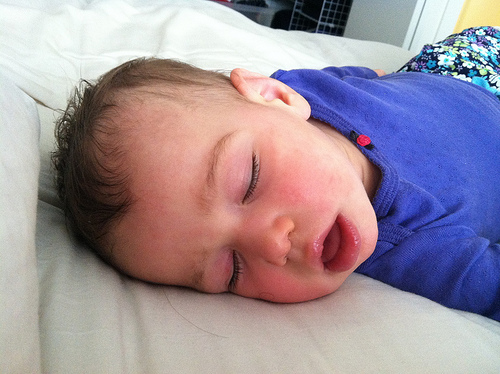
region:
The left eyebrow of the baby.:
[193, 235, 210, 292]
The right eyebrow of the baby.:
[207, 120, 234, 200]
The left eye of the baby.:
[221, 246, 243, 299]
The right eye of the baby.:
[244, 142, 261, 208]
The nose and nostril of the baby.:
[265, 210, 296, 277]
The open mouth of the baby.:
[307, 213, 363, 288]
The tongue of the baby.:
[323, 227, 339, 258]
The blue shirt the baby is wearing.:
[297, 50, 499, 292]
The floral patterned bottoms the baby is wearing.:
[402, 33, 499, 88]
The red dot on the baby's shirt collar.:
[349, 127, 379, 151]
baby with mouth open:
[71, 59, 397, 314]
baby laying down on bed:
[36, 81, 488, 337]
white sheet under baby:
[296, 309, 384, 372]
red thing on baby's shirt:
[353, 127, 394, 154]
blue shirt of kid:
[401, 89, 487, 191]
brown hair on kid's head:
[55, 86, 166, 226]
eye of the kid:
[226, 150, 284, 217]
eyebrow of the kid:
[184, 130, 242, 232]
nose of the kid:
[248, 204, 300, 276]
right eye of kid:
[211, 240, 251, 308]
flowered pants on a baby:
[397, 20, 497, 96]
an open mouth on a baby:
[305, 215, 360, 275]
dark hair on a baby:
[55, 60, 226, 270]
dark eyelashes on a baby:
[242, 152, 262, 199]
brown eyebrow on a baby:
[200, 126, 236, 191]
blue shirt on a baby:
[275, 50, 495, 307]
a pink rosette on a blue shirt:
[350, 127, 375, 147]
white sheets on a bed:
[36, 5, 488, 366]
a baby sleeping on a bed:
[50, 0, 495, 325]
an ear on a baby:
[221, 66, 311, 116]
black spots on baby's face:
[270, 127, 311, 187]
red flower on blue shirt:
[335, 116, 411, 158]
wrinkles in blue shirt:
[433, 191, 478, 233]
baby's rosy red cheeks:
[278, 155, 340, 220]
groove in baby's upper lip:
[289, 235, 317, 260]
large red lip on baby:
[338, 197, 378, 303]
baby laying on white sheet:
[48, 284, 242, 364]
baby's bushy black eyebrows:
[183, 138, 252, 210]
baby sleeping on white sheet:
[45, 58, 498, 288]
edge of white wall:
[386, 6, 446, 44]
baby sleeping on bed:
[78, 32, 440, 334]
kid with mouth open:
[147, 86, 384, 302]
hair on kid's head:
[57, 68, 167, 221]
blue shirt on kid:
[375, 70, 462, 212]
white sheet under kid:
[266, 291, 394, 372]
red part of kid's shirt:
[348, 125, 386, 155]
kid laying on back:
[55, 66, 487, 311]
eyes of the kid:
[175, 143, 282, 310]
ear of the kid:
[226, 60, 346, 130]